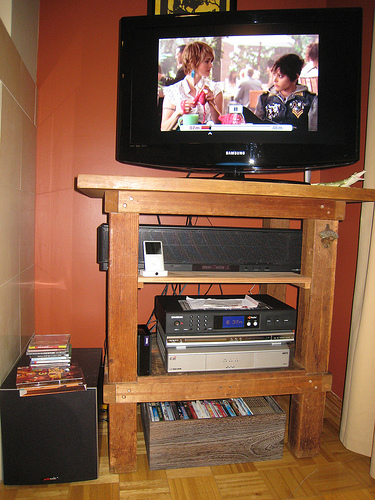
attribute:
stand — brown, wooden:
[66, 173, 370, 471]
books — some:
[149, 400, 258, 418]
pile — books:
[10, 367, 87, 396]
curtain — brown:
[337, 44, 374, 478]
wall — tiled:
[3, 10, 41, 330]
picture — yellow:
[148, 0, 235, 13]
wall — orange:
[42, 15, 105, 150]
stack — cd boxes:
[27, 334, 74, 366]